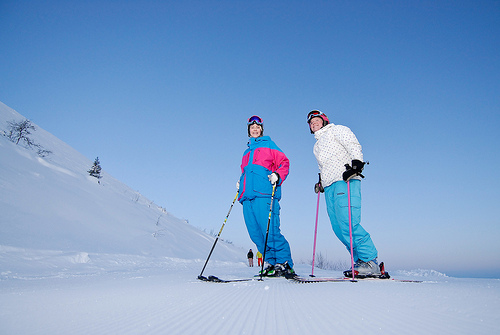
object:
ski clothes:
[311, 123, 378, 263]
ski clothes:
[235, 137, 295, 268]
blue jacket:
[237, 135, 290, 203]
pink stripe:
[242, 146, 292, 185]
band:
[319, 115, 329, 127]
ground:
[381, 126, 454, 175]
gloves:
[342, 159, 367, 182]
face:
[309, 116, 323, 132]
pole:
[198, 183, 240, 276]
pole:
[259, 182, 277, 280]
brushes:
[4, 117, 54, 158]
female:
[238, 116, 294, 279]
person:
[256, 251, 264, 267]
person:
[246, 248, 254, 267]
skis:
[290, 261, 425, 283]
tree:
[5, 117, 34, 147]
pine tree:
[88, 156, 103, 180]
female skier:
[305, 108, 385, 277]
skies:
[5, 7, 492, 277]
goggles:
[247, 115, 264, 124]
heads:
[246, 114, 264, 137]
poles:
[346, 180, 355, 281]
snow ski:
[198, 274, 255, 284]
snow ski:
[289, 274, 362, 284]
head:
[305, 109, 330, 135]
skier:
[298, 97, 394, 277]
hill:
[0, 103, 261, 281]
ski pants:
[242, 196, 293, 266]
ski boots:
[345, 257, 391, 279]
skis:
[198, 269, 294, 283]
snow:
[4, 104, 495, 332]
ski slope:
[3, 105, 499, 335]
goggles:
[305, 109, 322, 123]